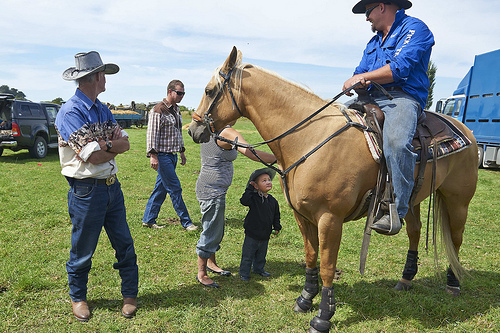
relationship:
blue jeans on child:
[239, 235, 269, 281] [239, 165, 282, 281]